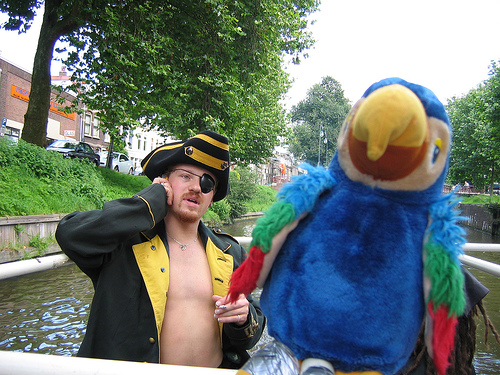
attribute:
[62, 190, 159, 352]
coat — man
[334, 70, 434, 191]
beak — brown , Yellow 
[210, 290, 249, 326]
hand — part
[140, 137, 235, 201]
hat — pirate, yellow, black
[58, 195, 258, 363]
jacket — pirate, yellow, black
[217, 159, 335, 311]
parrot wings — blue, green, red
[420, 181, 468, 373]
wing — Blue, green , red 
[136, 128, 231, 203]
hat — YELLOW , Black 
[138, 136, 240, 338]
man — shirtless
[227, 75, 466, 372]
parrot toy — blue, stuffed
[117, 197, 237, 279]
necklace — part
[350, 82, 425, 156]
nose — yellow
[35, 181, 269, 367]
jacket — black , yellow 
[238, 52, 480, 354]
bird — blue , Large 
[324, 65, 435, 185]
beak — yellow